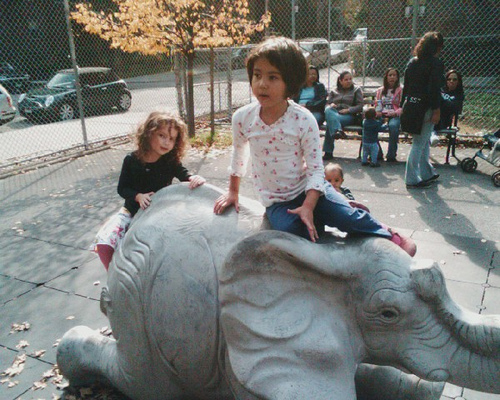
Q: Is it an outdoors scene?
A: Yes, it is outdoors.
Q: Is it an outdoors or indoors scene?
A: It is outdoors.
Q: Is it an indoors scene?
A: No, it is outdoors.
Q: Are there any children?
A: Yes, there is a child.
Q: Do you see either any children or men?
A: Yes, there is a child.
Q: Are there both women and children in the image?
A: Yes, there are both a child and a woman.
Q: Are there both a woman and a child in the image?
A: Yes, there are both a child and a woman.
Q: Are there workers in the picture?
A: No, there are no workers.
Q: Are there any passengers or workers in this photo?
A: No, there are no workers or passengers.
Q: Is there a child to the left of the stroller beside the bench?
A: Yes, there is a child to the left of the stroller.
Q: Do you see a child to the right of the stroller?
A: No, the child is to the left of the stroller.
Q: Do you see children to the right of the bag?
A: No, the child is to the left of the bag.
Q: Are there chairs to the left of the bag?
A: No, there is a child to the left of the bag.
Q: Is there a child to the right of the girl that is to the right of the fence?
A: Yes, there is a child to the right of the girl.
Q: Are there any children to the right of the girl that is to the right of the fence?
A: Yes, there is a child to the right of the girl.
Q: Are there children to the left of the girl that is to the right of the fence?
A: No, the child is to the right of the girl.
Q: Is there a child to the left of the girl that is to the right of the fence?
A: No, the child is to the right of the girl.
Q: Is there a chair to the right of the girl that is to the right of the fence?
A: No, there is a child to the right of the girl.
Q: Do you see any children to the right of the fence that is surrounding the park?
A: Yes, there is a child to the right of the fence.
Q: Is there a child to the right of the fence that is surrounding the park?
A: Yes, there is a child to the right of the fence.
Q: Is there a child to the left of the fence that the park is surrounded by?
A: No, the child is to the right of the fence.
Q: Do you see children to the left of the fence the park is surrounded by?
A: No, the child is to the right of the fence.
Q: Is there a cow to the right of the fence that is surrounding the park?
A: No, there is a child to the right of the fence.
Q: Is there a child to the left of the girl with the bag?
A: Yes, there is a child to the left of the girl.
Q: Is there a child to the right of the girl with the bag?
A: No, the child is to the left of the girl.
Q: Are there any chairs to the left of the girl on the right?
A: No, there is a child to the left of the girl.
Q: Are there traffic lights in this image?
A: No, there are no traffic lights.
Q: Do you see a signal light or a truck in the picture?
A: No, there are no traffic lights or trucks.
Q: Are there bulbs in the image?
A: No, there are no bulbs.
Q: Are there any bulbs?
A: No, there are no bulbs.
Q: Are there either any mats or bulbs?
A: No, there are no bulbs or mats.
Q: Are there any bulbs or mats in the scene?
A: No, there are no bulbs or mats.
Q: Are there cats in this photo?
A: No, there are no cats.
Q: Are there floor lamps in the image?
A: No, there are no floor lamps.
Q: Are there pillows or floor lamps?
A: No, there are no floor lamps or pillows.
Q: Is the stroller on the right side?
A: Yes, the stroller is on the right of the image.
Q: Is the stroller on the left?
A: No, the stroller is on the right of the image.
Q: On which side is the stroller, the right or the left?
A: The stroller is on the right of the image.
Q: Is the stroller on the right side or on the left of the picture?
A: The stroller is on the right of the image.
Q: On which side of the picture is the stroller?
A: The stroller is on the right of the image.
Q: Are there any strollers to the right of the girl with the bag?
A: Yes, there is a stroller to the right of the girl.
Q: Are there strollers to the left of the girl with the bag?
A: No, the stroller is to the right of the girl.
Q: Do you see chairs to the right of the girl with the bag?
A: No, there is a stroller to the right of the girl.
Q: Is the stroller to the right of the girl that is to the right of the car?
A: Yes, the stroller is to the right of the girl.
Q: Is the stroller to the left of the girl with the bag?
A: No, the stroller is to the right of the girl.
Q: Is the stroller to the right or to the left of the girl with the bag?
A: The stroller is to the right of the girl.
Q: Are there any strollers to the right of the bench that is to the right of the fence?
A: Yes, there is a stroller to the right of the bench.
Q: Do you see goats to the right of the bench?
A: No, there is a stroller to the right of the bench.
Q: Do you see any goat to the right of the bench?
A: No, there is a stroller to the right of the bench.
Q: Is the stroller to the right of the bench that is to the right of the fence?
A: Yes, the stroller is to the right of the bench.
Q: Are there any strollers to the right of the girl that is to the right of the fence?
A: Yes, there is a stroller to the right of the girl.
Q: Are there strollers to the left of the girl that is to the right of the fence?
A: No, the stroller is to the right of the girl.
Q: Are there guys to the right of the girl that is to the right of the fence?
A: No, there is a stroller to the right of the girl.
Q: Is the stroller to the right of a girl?
A: Yes, the stroller is to the right of a girl.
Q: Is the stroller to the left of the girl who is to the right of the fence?
A: No, the stroller is to the right of the girl.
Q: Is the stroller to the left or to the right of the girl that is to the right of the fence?
A: The stroller is to the right of the girl.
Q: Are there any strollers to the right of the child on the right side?
A: Yes, there is a stroller to the right of the kid.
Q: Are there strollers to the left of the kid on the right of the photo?
A: No, the stroller is to the right of the child.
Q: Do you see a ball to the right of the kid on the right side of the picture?
A: No, there is a stroller to the right of the kid.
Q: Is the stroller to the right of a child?
A: Yes, the stroller is to the right of a child.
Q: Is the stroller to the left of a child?
A: No, the stroller is to the right of a child.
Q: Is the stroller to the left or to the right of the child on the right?
A: The stroller is to the right of the child.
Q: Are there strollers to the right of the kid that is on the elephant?
A: Yes, there is a stroller to the right of the kid.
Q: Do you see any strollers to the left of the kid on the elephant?
A: No, the stroller is to the right of the kid.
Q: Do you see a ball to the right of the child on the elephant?
A: No, there is a stroller to the right of the child.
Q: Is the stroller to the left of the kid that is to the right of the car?
A: No, the stroller is to the right of the child.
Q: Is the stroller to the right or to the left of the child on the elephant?
A: The stroller is to the right of the kid.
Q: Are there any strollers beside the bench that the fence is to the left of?
A: Yes, there is a stroller beside the bench.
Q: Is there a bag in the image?
A: Yes, there is a bag.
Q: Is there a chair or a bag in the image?
A: Yes, there is a bag.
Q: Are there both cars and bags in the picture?
A: Yes, there are both a bag and a car.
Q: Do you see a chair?
A: No, there are no chairs.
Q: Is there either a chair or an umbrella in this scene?
A: No, there are no chairs or umbrellas.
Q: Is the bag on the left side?
A: No, the bag is on the right of the image.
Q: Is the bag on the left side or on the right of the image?
A: The bag is on the right of the image.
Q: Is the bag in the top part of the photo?
A: Yes, the bag is in the top of the image.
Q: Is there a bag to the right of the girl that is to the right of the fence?
A: Yes, there is a bag to the right of the girl.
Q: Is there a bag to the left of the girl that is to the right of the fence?
A: No, the bag is to the right of the girl.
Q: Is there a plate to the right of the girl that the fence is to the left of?
A: No, there is a bag to the right of the girl.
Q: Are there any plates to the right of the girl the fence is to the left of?
A: No, there is a bag to the right of the girl.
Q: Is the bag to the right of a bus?
A: No, the bag is to the right of the girl.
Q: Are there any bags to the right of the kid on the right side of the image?
A: Yes, there is a bag to the right of the kid.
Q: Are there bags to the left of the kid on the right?
A: No, the bag is to the right of the child.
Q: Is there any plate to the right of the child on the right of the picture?
A: No, there is a bag to the right of the child.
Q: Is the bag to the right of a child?
A: Yes, the bag is to the right of a child.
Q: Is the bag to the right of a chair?
A: No, the bag is to the right of a child.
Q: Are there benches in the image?
A: Yes, there is a bench.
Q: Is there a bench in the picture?
A: Yes, there is a bench.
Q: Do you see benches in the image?
A: Yes, there is a bench.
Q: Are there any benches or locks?
A: Yes, there is a bench.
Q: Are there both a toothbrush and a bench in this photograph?
A: No, there is a bench but no toothbrushes.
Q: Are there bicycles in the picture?
A: No, there are no bicycles.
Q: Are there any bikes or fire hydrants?
A: No, there are no bikes or fire hydrants.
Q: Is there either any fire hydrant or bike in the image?
A: No, there are no bikes or fire hydrants.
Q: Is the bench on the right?
A: Yes, the bench is on the right of the image.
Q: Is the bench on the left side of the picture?
A: No, the bench is on the right of the image.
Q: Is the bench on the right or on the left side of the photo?
A: The bench is on the right of the image.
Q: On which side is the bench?
A: The bench is on the right of the image.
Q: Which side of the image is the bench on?
A: The bench is on the right of the image.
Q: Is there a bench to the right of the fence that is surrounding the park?
A: Yes, there is a bench to the right of the fence.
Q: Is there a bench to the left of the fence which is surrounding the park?
A: No, the bench is to the right of the fence.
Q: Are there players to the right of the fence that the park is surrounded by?
A: No, there is a bench to the right of the fence.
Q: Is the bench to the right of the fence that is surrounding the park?
A: Yes, the bench is to the right of the fence.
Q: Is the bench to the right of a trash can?
A: No, the bench is to the right of the fence.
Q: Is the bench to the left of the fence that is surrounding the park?
A: No, the bench is to the right of the fence.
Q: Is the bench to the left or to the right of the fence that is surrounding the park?
A: The bench is to the right of the fence.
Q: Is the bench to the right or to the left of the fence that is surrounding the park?
A: The bench is to the right of the fence.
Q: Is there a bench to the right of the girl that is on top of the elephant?
A: Yes, there is a bench to the right of the girl.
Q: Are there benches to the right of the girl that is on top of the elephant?
A: Yes, there is a bench to the right of the girl.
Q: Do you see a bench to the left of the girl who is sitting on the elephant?
A: No, the bench is to the right of the girl.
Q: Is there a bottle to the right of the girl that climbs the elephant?
A: No, there is a bench to the right of the girl.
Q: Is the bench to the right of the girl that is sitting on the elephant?
A: Yes, the bench is to the right of the girl.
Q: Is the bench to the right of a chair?
A: No, the bench is to the right of the girl.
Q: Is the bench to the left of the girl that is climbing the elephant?
A: No, the bench is to the right of the girl.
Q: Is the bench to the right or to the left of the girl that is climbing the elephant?
A: The bench is to the right of the girl.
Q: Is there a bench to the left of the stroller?
A: Yes, there is a bench to the left of the stroller.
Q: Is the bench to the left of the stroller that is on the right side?
A: Yes, the bench is to the left of the stroller.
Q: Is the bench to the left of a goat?
A: No, the bench is to the left of the stroller.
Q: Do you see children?
A: Yes, there is a child.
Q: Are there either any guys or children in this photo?
A: Yes, there is a child.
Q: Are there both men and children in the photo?
A: No, there is a child but no men.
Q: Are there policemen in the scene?
A: No, there are no policemen.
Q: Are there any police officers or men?
A: No, there are no police officers or men.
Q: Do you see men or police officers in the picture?
A: No, there are no police officers or men.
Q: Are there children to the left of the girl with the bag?
A: Yes, there is a child to the left of the girl.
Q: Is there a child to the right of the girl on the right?
A: No, the child is to the left of the girl.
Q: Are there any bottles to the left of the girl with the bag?
A: No, there is a child to the left of the girl.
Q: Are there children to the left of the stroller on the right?
A: Yes, there is a child to the left of the stroller.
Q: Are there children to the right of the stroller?
A: No, the child is to the left of the stroller.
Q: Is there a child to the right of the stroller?
A: No, the child is to the left of the stroller.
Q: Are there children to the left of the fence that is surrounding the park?
A: No, the child is to the right of the fence.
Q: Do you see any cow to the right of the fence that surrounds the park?
A: No, there is a child to the right of the fence.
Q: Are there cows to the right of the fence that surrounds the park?
A: No, there is a child to the right of the fence.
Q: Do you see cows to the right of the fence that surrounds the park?
A: No, there is a child to the right of the fence.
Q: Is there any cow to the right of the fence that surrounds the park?
A: No, there is a child to the right of the fence.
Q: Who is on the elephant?
A: The kid is on the elephant.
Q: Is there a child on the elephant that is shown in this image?
A: Yes, there is a child on the elephant.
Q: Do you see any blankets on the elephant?
A: No, there is a child on the elephant.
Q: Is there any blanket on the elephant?
A: No, there is a child on the elephant.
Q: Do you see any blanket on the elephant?
A: No, there is a child on the elephant.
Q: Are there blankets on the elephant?
A: No, there is a child on the elephant.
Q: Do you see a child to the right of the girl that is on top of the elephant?
A: Yes, there is a child to the right of the girl.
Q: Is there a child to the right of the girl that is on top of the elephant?
A: Yes, there is a child to the right of the girl.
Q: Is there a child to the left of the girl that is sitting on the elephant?
A: No, the child is to the right of the girl.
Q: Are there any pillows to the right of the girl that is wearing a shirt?
A: No, there is a child to the right of the girl.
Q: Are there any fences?
A: Yes, there is a fence.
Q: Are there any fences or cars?
A: Yes, there is a fence.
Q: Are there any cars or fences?
A: Yes, there is a fence.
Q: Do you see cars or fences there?
A: Yes, there is a fence.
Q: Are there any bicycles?
A: No, there are no bicycles.